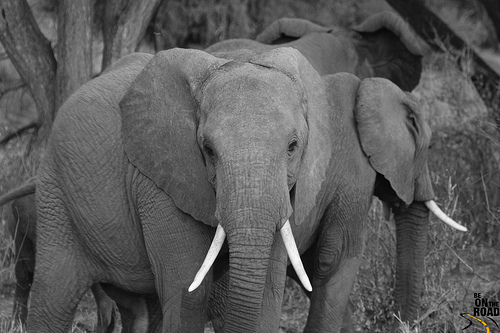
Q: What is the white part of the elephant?
A: Tusk.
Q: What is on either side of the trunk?
A: Tusks.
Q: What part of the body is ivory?
A: Tusks.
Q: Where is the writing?
A: Bottom right.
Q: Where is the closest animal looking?
A: At the camera.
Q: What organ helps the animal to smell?
A: Trunk.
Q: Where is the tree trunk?
A: Behind the closer animal.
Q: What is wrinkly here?
A: Animals' skin.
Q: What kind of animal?
A: Elephant.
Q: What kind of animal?
A: Elephant.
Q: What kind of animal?
A: Elephant.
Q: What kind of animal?
A: Elephant.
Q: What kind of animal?
A: Elephant.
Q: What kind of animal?
A: Elephant.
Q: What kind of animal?
A: Elephant.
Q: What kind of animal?
A: Elephant.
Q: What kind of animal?
A: Elephant.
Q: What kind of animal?
A: Elephant.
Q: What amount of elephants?
A: Three.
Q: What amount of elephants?
A: Three.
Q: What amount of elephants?
A: Three.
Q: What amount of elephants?
A: Three.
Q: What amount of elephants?
A: Three.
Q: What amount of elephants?
A: Three.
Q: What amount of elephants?
A: Three.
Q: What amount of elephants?
A: Three.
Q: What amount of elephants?
A: Three.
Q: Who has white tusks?
A: Elephant.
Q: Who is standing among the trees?
A: Elephants.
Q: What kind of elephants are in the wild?
A: African.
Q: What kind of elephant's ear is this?
A: African.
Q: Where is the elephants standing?
A: Bush.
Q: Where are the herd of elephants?
A: In brush.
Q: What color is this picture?
A: Black and white.